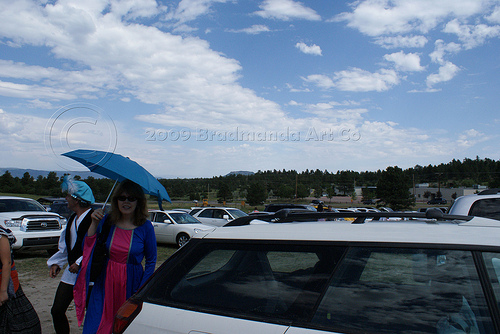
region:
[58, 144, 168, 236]
Blue umbrella being held.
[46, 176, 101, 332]
Person in a blue hat.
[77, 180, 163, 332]
Girl in a red and blue dress.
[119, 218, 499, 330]
White vehicle next to woman.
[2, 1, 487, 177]
Clouds in the sky.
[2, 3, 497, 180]
Blue skies with clouds.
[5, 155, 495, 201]
Trees in the background.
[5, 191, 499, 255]
Cars in a parking lot.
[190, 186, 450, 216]
People in the background.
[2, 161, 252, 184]
Mountains in the background.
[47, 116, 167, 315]
woman holding an umbrella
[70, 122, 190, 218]
the umbrella is blue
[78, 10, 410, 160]
the sky is partly cloudy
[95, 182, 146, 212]
woman wearing sun glasses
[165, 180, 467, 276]
the cars are parked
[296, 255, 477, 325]
reflection on car window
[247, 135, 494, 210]
green bushy trees in the background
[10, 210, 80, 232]
the headlights are off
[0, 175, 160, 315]
other people walking with the woman with the umbrella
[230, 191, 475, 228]
rack on the roof of the car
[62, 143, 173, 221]
a large blue umbrella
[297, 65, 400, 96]
a small section of white clouds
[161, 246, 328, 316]
part of a car window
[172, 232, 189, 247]
the tire of a car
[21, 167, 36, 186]
a tall green tree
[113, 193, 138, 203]
a woman's black sunglasses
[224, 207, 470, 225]
a black car rack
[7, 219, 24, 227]
a truck headlight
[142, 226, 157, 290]
the arm of a woman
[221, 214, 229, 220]
a white side mirror of an suv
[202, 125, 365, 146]
The name is Bradmanda Art Co.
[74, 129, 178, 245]
The woman has a umbrella.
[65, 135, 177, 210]
The umbrella is blue.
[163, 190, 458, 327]
The car is white.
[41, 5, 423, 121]
Clouds are in the sky.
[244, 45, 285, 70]
The sky is blue.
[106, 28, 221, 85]
The clouds are white.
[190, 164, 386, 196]
Pine trees in the background.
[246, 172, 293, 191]
The trees are dark green.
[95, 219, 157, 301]
The dress is pink and blue.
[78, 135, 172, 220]
woman carrying blue umbrella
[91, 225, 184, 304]
woman wearing blue and pink dress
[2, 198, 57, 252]
white pick up in background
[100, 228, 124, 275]
woman carrying black purse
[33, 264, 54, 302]
tan sand on ground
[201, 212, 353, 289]
white station wagon by woman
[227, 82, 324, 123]
blue sky with fluffy clouds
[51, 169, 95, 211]
person with blue head gear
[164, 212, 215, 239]
white coupe in parking lot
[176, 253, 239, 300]
glass window in white car